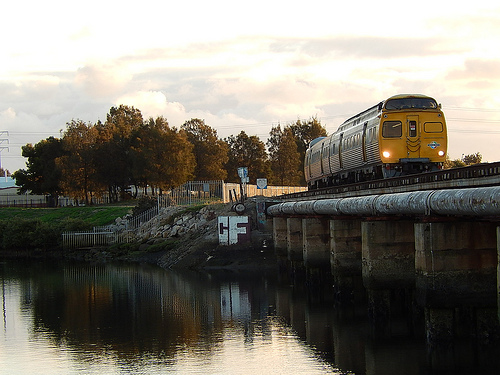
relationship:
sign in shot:
[256, 178, 268, 189] [0, 0, 499, 374]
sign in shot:
[239, 166, 246, 178] [0, 0, 499, 374]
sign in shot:
[242, 176, 250, 183] [0, 0, 499, 374]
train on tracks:
[304, 93, 448, 189] [278, 160, 499, 201]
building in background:
[2, 174, 24, 197] [1, 0, 302, 205]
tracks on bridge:
[278, 160, 499, 201] [268, 162, 499, 298]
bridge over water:
[268, 162, 499, 298] [0, 255, 498, 374]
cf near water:
[219, 215, 249, 244] [0, 255, 498, 374]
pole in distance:
[0, 128, 10, 152] [0, 0, 499, 205]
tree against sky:
[52, 119, 99, 206] [1, 0, 499, 175]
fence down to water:
[61, 178, 224, 250] [0, 255, 498, 374]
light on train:
[385, 152, 391, 159] [304, 93, 448, 189]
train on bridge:
[304, 93, 448, 189] [268, 162, 499, 298]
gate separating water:
[62, 226, 132, 250] [0, 255, 498, 374]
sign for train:
[256, 178, 268, 189] [304, 93, 448, 189]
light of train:
[385, 152, 391, 159] [304, 93, 448, 189]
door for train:
[408, 117, 419, 160] [304, 93, 448, 189]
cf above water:
[219, 215, 249, 244] [0, 255, 498, 374]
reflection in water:
[221, 280, 251, 319] [0, 255, 498, 374]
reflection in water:
[22, 265, 271, 373] [0, 255, 498, 374]